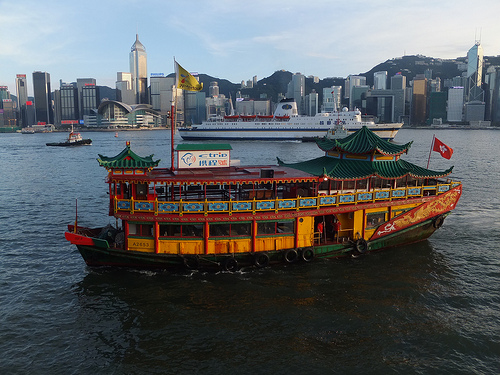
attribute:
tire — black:
[352, 234, 369, 251]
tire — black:
[299, 242, 316, 264]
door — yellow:
[267, 201, 367, 251]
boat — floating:
[35, 157, 492, 266]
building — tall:
[57, 85, 99, 122]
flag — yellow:
[170, 59, 210, 97]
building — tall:
[380, 72, 413, 122]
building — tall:
[129, 39, 149, 104]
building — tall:
[317, 81, 379, 106]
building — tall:
[35, 10, 485, 177]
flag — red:
[433, 136, 454, 159]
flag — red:
[430, 132, 457, 162]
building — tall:
[282, 67, 314, 118]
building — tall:
[127, 31, 157, 108]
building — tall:
[463, 41, 485, 122]